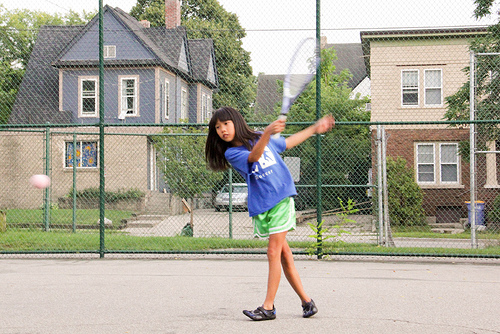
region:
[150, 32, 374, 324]
A girl playing tennis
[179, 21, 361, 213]
A girl holding a tennis racket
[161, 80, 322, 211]
A girl with long hair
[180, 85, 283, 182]
A girl with dark hair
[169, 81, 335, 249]
A girl wearing a blue shirt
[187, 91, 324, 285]
A girl wearing green shorts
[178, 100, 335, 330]
A girl wearing black shoes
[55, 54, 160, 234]
A chain link fence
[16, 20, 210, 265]
A house behind a chain link fence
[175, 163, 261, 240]
A car in a driveway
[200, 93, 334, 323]
this is a girl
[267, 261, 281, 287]
the girl is light skinned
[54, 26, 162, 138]
this is a house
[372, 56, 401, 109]
this is a wall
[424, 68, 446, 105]
this is a window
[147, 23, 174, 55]
this is the roof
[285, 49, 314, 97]
this is a racket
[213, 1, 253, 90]
this is a tree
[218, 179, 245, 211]
this is a car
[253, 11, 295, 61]
this is the sky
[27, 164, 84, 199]
a white tennis ball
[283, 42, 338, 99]
top portion of tennis racket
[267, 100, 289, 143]
the hand holding tennis racket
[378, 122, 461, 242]
part of the gray fence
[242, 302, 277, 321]
a shoe worn by girl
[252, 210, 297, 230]
green shorts on girl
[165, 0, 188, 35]
a brown chimney on house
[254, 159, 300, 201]
part of blue and white top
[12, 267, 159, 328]
part of the tennis floor court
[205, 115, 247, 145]
face of girl playing tennis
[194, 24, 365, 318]
little girl playing tennis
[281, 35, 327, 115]
girl holding a tennis racket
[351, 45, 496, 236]
a green iron fence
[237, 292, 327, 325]
girl wearing black sneakers without socks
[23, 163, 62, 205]
white tennis ball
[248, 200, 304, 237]
girl wearing green shorts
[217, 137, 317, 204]
girl wearing blue T-shirt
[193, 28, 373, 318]
girl playing tennis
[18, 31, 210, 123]
a house with a blue roof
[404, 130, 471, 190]
a brick wall with a window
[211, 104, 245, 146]
the head of a girl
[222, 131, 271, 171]
the arm of a girl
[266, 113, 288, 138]
the hand of a girl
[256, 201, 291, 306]
the leg of a girl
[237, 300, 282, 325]
a black shoe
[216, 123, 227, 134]
the nose of the girl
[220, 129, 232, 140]
the mouth of the girl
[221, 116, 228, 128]
the eye of the girl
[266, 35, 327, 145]
a white tennis racket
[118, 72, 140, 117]
a window on the house